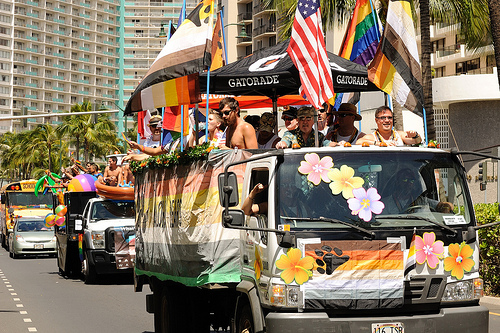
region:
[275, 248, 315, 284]
orange flower on truck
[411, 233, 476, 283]
pink and orange flower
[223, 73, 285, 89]
white writing that says GATORADE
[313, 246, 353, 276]
black paw print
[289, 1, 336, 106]
American flag on top of a truck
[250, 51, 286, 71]
white and orange GATORADE symbol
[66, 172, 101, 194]
large colorful beach ball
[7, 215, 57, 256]
gray compact car driving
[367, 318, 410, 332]
part of a license plate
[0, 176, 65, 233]
school bus down the street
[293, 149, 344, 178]
pink flower on front of truck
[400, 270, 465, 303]
black grill on front of truck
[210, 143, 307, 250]
black side mirrors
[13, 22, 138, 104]
large condo complex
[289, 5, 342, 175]
large American flag on truck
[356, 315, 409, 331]
white license plate on front of truck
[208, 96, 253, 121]
man wearing dark glasse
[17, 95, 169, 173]
large cluster of palm trees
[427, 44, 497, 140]
white balcony on front of building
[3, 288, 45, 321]
broken white lines on street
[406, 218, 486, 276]
Pink and orange flower on a truck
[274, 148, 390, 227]
Three flowers on a truck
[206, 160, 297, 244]
Mirror on a truck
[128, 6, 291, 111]
Flag on a truck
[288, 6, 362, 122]
American flag on a truck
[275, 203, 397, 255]
Wiper on a truck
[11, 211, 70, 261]
Silver car on a road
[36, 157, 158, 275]
Truck full of people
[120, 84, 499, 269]
Truck with flags full of people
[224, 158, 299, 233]
Arm outside of a truck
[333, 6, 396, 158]
Rainbow flag on truck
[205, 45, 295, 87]
Black and white Gatorade tent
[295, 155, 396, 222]
Three flowers on truck windshield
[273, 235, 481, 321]
Three flowers on front of truck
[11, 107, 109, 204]
Palm trees beside cars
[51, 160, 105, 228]
Multi-colored beach ball on truck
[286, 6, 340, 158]
American flag on truck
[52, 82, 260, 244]
Two open trucks full of people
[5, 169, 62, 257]
Yellow school bus following gray car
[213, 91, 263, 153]
Shirtless man with black sunglasses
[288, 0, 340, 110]
American flag on top of the truck.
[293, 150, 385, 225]
Three flowers on the window of the truck.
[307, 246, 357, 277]
Animal paw print on the banner in front of the truck.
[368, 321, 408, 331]
The license plate on the bumper of the truck.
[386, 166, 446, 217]
Man driving the truck.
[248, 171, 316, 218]
Man sitting on the passenger side inside of the truck.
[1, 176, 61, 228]
Yellow school bus in the parade line.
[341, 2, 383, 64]
Rainbow flag next to the Gatorade umbrella on the back of the truck.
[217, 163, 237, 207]
Top side view mirror on the truck.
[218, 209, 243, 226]
Bottom side view mirror on the truck.